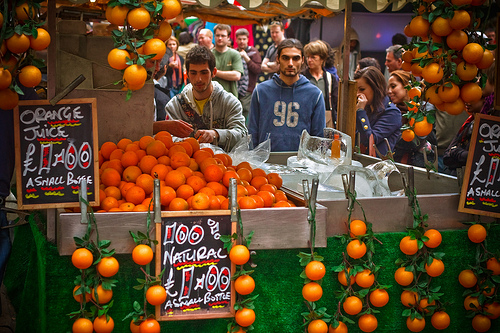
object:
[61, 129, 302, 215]
pile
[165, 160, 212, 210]
orange orange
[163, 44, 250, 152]
man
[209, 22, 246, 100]
man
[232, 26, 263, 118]
man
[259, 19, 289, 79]
man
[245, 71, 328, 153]
shirt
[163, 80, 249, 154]
shirt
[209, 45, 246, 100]
shirt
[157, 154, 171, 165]
oranges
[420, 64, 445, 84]
orange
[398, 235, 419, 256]
orange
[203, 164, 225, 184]
orange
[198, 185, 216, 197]
orange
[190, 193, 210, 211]
orange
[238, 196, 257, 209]
orange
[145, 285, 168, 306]
oranges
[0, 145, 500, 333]
stand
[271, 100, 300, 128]
96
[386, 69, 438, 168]
people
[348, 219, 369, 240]
orange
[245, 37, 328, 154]
people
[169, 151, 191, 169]
orange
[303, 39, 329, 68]
hair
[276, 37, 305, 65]
hair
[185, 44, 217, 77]
hair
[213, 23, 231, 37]
hair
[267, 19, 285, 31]
hair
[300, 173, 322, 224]
scissor hook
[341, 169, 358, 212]
scissor hook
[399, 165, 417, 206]
scissor hook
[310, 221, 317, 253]
vine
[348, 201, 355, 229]
vine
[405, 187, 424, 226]
vine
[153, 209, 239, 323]
sign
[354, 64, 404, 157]
people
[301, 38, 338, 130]
people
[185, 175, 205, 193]
oranges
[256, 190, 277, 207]
oranges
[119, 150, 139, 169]
oranges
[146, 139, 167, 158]
oranges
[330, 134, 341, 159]
orange top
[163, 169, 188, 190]
orange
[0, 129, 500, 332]
orange stand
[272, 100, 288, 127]
number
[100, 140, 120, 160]
oranges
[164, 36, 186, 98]
patrons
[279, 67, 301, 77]
beard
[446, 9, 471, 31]
oranges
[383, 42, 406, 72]
people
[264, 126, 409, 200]
equipment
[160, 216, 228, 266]
100% natural